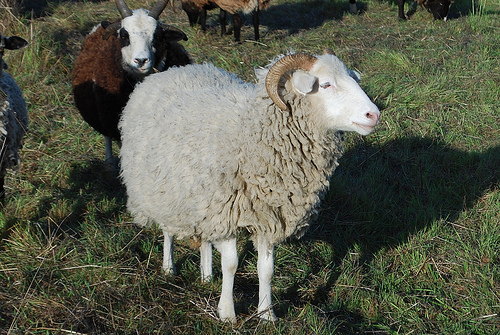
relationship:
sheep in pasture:
[113, 51, 385, 334] [2, 1, 500, 329]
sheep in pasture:
[76, 2, 197, 168] [2, 1, 500, 329]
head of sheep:
[270, 50, 384, 131] [113, 51, 385, 334]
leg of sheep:
[213, 239, 238, 324] [113, 51, 385, 334]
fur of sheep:
[134, 72, 321, 226] [113, 51, 385, 334]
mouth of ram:
[353, 118, 378, 135] [113, 51, 385, 334]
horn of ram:
[263, 54, 316, 106] [113, 51, 385, 334]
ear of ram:
[291, 68, 317, 95] [113, 51, 385, 334]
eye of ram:
[318, 81, 332, 91] [113, 51, 385, 334]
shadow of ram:
[300, 129, 497, 305] [113, 51, 385, 334]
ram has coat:
[113, 51, 385, 334] [134, 72, 321, 226]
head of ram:
[270, 50, 384, 131] [113, 51, 385, 334]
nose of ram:
[364, 104, 382, 120] [113, 51, 385, 334]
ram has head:
[76, 2, 197, 168] [103, 8, 181, 77]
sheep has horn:
[113, 51, 385, 334] [263, 54, 316, 106]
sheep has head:
[113, 51, 385, 334] [270, 50, 384, 131]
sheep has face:
[113, 51, 385, 334] [311, 49, 380, 136]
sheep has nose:
[113, 51, 385, 334] [364, 104, 382, 120]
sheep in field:
[113, 51, 385, 334] [2, 1, 500, 329]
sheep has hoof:
[113, 51, 385, 334] [218, 312, 236, 323]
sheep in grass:
[113, 51, 385, 334] [2, 1, 500, 329]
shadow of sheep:
[300, 129, 497, 305] [113, 51, 385, 334]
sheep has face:
[76, 2, 197, 168] [115, 13, 162, 69]